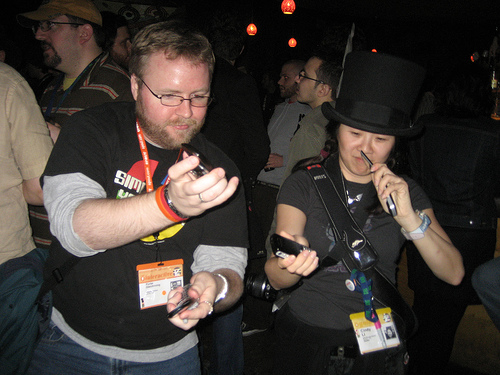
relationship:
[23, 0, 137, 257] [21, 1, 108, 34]
man wears cap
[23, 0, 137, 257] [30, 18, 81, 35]
man wears glasses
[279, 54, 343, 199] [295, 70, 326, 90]
man wears glasses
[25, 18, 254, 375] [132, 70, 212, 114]
man wears glasses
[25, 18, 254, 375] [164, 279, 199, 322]
man holding phone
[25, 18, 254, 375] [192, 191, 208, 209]
man wears ring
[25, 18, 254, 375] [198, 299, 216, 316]
man wears ring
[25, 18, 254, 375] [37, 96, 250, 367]
man wears shirt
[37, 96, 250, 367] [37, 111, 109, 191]
shirt has sleeve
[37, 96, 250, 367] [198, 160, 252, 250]
shirt has sleeve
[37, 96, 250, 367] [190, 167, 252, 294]
shirt has sleeve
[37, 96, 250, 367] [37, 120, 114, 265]
shirt has sleeve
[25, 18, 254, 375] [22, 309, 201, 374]
man wears jeans